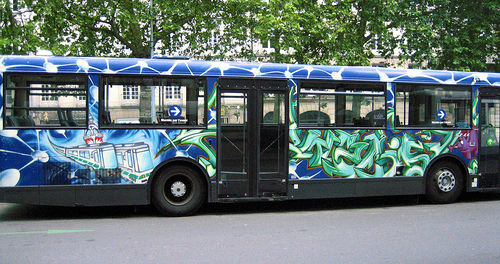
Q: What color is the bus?
A: Blue.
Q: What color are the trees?
A: Green.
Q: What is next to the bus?
A: Trees.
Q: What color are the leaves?
A: Green.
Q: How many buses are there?
A: One.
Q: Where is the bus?
A: On the street.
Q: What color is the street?
A: Gray.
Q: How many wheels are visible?
A: Two.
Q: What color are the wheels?
A: Black.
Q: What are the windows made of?
A: Glass.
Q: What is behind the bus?
A: Trees.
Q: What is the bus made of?
A: Metal.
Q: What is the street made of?
A: Asphalt.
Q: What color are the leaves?
A: Green.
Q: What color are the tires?
A: Black.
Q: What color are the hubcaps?
A: Gray.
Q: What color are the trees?
A: Green.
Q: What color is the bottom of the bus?
A: Black.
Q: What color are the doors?
A: Black.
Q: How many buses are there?
A: One.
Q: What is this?
A: A bus.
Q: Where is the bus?
A: On the street.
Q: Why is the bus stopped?
A: Waiting for passengers.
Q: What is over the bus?
A: Trees.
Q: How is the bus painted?
A: With colorful designs.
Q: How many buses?
A: One.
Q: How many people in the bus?
A: None.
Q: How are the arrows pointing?
A: Right.